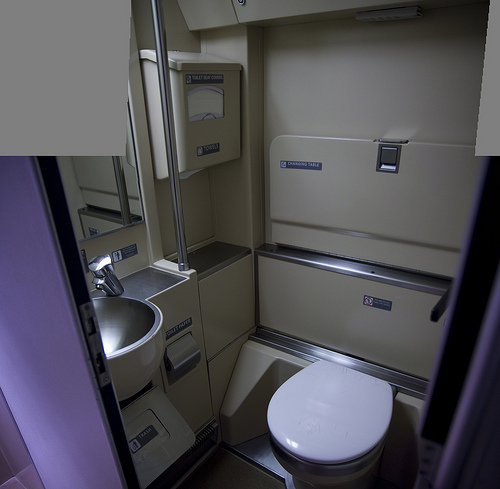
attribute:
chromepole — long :
[133, 3, 203, 279]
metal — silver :
[258, 256, 445, 295]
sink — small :
[78, 281, 162, 378]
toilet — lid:
[260, 338, 405, 487]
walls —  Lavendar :
[388, 157, 498, 487]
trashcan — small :
[167, 238, 249, 276]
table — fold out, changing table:
[251, 106, 468, 361]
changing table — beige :
[246, 129, 494, 241]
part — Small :
[195, 241, 264, 268]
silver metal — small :
[375, 142, 402, 168]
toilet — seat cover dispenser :
[256, 348, 397, 483]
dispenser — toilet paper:
[161, 325, 200, 388]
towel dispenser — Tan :
[134, 48, 239, 178]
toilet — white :
[266, 350, 384, 469]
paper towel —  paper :
[183, 84, 235, 146]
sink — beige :
[88, 291, 164, 358]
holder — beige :
[139, 44, 247, 177]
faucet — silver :
[87, 250, 127, 301]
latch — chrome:
[370, 134, 404, 175]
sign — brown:
[126, 422, 157, 453]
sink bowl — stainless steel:
[87, 290, 163, 402]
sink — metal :
[90, 250, 193, 388]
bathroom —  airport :
[6, 9, 483, 478]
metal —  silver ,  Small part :
[90, 260, 130, 302]